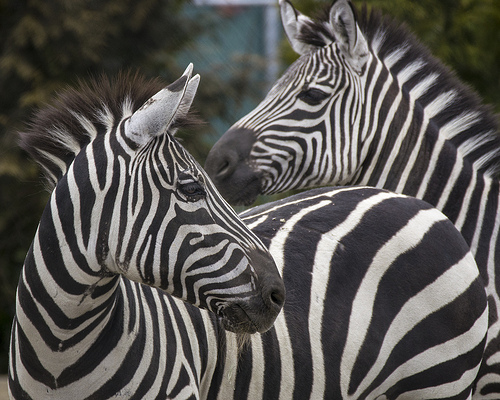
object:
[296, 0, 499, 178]
mane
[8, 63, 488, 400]
zebra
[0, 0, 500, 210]
ground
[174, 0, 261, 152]
wall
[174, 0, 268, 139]
building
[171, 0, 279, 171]
fence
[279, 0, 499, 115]
trees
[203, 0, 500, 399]
zebra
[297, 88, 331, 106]
dark eye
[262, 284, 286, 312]
black nose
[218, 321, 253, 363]
whiskers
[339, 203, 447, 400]
stripes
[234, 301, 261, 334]
mouth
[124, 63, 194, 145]
ears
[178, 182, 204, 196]
eye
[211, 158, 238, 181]
nose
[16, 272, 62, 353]
stripes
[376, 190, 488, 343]
hind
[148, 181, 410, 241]
back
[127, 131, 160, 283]
stripes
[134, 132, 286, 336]
face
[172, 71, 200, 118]
ears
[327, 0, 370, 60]
ears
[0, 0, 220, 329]
trees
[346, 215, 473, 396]
stripes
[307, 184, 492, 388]
rump